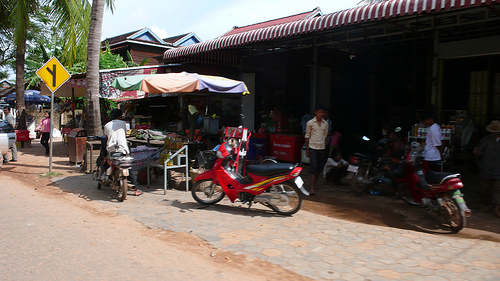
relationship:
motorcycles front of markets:
[101, 141, 472, 239] [154, 0, 497, 162]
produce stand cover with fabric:
[154, 0, 497, 162] [156, 0, 499, 62]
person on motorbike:
[95, 103, 136, 176] [96, 153, 135, 206]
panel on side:
[101, 68, 254, 111] [75, 101, 283, 208]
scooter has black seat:
[188, 144, 312, 224] [241, 158, 301, 180]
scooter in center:
[188, 144, 312, 224] [63, 157, 347, 260]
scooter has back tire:
[188, 144, 312, 224] [262, 175, 308, 218]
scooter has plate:
[188, 144, 312, 224] [293, 173, 306, 189]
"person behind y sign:
[34, 109, 57, 159] [28, 53, 79, 96]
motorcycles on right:
[353, 159, 471, 230] [245, 121, 499, 226]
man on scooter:
[95, 103, 136, 176] [96, 153, 135, 206]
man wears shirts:
[415, 106, 445, 180] [422, 123, 445, 164]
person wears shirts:
[415, 106, 445, 180] [422, 123, 445, 164]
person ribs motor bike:
[95, 103, 136, 176] [96, 153, 135, 206]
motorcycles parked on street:
[353, 159, 471, 230] [10, 136, 485, 281]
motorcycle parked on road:
[188, 144, 312, 224] [10, 136, 485, 281]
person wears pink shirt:
[34, 109, 57, 159] [34, 117, 54, 133]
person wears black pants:
[415, 106, 445, 180] [423, 160, 444, 188]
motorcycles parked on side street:
[353, 159, 471, 230] [245, 121, 499, 226]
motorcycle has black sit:
[188, 144, 312, 224] [241, 158, 301, 180]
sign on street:
[28, 53, 79, 96] [10, 136, 485, 281]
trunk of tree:
[78, 1, 108, 138] [58, 1, 128, 53]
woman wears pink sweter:
[34, 109, 57, 159] [34, 117, 54, 133]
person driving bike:
[95, 103, 136, 176] [96, 153, 135, 206]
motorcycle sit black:
[188, 144, 312, 224] [241, 158, 301, 180]